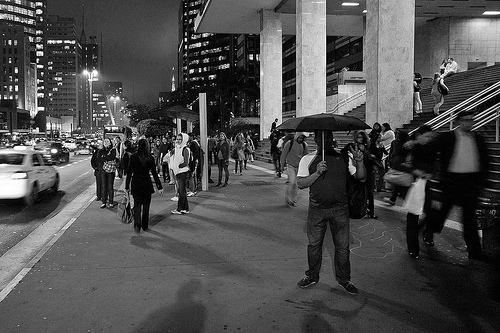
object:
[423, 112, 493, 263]
man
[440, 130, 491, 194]
suit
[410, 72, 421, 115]
man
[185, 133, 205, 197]
man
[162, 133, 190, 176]
hoodie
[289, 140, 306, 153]
backpack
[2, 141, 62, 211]
taxi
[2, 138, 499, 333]
street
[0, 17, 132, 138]
lights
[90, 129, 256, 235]
crowd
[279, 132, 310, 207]
man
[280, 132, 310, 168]
hoodie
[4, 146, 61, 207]
cab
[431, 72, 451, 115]
woman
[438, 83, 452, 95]
bag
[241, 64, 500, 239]
stairs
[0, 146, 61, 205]
car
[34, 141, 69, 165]
vehicle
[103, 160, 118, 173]
bag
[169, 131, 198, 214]
boy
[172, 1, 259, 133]
buildings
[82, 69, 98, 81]
street light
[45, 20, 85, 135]
building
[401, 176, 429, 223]
grocery bag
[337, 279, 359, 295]
shoe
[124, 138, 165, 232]
people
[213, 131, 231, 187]
people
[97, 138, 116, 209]
people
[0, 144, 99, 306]
road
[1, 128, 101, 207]
traffic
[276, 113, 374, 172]
umbrella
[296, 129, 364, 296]
man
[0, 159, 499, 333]
tarmac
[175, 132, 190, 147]
hood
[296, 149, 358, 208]
shirt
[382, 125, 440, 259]
woman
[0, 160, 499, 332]
sidewalk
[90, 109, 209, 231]
bus stop